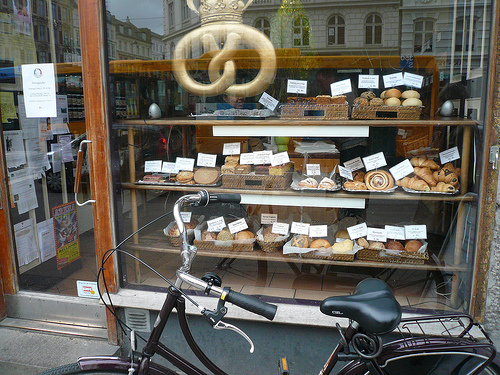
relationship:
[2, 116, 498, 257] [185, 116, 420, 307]
bakery window displays multiple items for sale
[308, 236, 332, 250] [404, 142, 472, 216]
pastry on display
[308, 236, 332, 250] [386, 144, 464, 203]
pastry on display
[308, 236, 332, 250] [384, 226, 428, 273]
pastry on display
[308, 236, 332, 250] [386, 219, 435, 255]
pastry on display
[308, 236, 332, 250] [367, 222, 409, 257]
pastry on display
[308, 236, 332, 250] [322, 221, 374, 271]
pastry on display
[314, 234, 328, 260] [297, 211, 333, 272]
pastry on display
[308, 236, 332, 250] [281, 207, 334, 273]
pastry on display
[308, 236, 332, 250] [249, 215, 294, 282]
pastry on display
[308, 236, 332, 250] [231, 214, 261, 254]
pastry on display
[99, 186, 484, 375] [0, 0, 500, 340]
bicycle in front of bakery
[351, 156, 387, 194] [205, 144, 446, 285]
rolls dplay in window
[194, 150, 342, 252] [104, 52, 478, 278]
goods for sale at window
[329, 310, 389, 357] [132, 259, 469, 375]
cable lock around seat post of bicycle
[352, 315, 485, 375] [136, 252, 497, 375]
luggage rack on bicycle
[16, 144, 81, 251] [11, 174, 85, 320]
posters display on store wall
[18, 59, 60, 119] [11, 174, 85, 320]
sign display on store wall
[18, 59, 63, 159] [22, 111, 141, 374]
sign on store front door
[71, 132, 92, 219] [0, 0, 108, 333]
handle for door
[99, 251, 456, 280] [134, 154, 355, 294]
tile floor in shop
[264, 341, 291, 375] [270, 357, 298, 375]
bike pedal side reflective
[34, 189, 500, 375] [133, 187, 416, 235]
bicycle parked by window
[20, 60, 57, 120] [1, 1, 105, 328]
paper diplasyed on door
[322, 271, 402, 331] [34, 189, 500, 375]
seat of bicycle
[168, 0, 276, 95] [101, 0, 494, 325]
display on window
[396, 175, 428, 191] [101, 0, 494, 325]
croissant on display on window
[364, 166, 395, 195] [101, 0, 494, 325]
rolls on display on window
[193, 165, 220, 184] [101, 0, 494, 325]
bread on display on window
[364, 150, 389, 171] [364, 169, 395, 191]
paper stuck onto bread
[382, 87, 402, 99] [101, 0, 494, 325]
bread on display on window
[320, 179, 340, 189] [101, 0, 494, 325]
bread on display on window